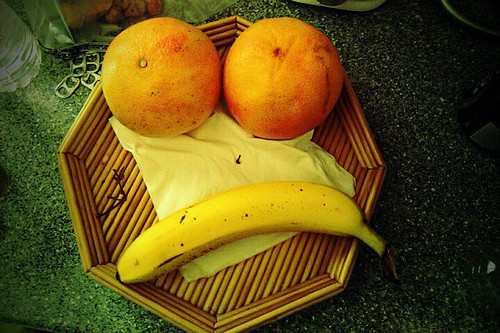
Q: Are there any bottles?
A: Yes, there is a bottle.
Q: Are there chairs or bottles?
A: Yes, there is a bottle.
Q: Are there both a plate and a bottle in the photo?
A: Yes, there are both a bottle and a plate.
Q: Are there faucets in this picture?
A: No, there are no faucets.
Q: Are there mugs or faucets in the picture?
A: No, there are no faucets or mugs.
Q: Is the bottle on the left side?
A: Yes, the bottle is on the left of the image.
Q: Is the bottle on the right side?
A: No, the bottle is on the left of the image.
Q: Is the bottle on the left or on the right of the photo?
A: The bottle is on the left of the image.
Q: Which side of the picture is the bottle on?
A: The bottle is on the left of the image.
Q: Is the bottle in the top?
A: Yes, the bottle is in the top of the image.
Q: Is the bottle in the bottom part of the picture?
A: No, the bottle is in the top of the image.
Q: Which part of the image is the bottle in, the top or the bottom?
A: The bottle is in the top of the image.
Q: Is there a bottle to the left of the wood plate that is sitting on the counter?
A: Yes, there is a bottle to the left of the plate.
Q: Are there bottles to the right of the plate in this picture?
A: No, the bottle is to the left of the plate.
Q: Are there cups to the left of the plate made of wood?
A: No, there is a bottle to the left of the plate.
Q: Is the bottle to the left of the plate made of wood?
A: Yes, the bottle is to the left of the plate.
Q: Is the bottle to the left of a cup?
A: No, the bottle is to the left of the plate.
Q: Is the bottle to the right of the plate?
A: No, the bottle is to the left of the plate.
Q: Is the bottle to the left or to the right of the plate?
A: The bottle is to the left of the plate.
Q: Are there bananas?
A: Yes, there is a banana.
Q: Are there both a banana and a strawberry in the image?
A: No, there is a banana but no strawberries.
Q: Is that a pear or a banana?
A: That is a banana.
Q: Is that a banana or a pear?
A: That is a banana.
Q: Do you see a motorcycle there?
A: No, there are no motorcycles.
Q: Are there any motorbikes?
A: No, there are no motorbikes.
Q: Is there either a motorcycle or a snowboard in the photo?
A: No, there are no motorcycles or snowboards.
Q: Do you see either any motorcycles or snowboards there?
A: No, there are no motorcycles or snowboards.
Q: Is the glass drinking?
A: Yes, the glass is drinking.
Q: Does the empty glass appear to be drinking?
A: Yes, the glass is drinking.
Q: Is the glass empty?
A: Yes, the glass is empty.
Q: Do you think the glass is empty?
A: Yes, the glass is empty.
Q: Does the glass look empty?
A: Yes, the glass is empty.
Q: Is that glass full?
A: No, the glass is empty.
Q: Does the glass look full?
A: No, the glass is empty.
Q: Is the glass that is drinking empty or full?
A: The glass is empty.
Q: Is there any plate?
A: Yes, there is a plate.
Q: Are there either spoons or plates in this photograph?
A: Yes, there is a plate.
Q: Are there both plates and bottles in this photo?
A: Yes, there are both a plate and a bottle.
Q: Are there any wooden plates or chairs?
A: Yes, there is a wood plate.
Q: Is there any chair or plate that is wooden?
A: Yes, the plate is wooden.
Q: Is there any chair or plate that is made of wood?
A: Yes, the plate is made of wood.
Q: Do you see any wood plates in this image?
A: Yes, there is a wood plate.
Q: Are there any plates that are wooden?
A: Yes, there is a plate that is wooden.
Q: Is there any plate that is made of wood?
A: Yes, there is a plate that is made of wood.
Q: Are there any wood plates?
A: Yes, there is a plate that is made of wood.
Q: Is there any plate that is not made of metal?
A: Yes, there is a plate that is made of wood.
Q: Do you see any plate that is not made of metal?
A: Yes, there is a plate that is made of wood.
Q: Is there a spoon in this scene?
A: No, there are no spoons.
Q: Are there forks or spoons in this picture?
A: No, there are no spoons or forks.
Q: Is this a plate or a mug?
A: This is a plate.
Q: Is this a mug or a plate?
A: This is a plate.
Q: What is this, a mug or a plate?
A: This is a plate.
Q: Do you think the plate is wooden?
A: Yes, the plate is wooden.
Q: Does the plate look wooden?
A: Yes, the plate is wooden.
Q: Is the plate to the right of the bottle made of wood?
A: Yes, the plate is made of wood.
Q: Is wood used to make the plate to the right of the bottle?
A: Yes, the plate is made of wood.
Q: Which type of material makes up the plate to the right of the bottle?
A: The plate is made of wood.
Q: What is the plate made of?
A: The plate is made of wood.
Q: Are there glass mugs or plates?
A: No, there is a plate but it is wooden.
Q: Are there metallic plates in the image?
A: No, there is a plate but it is wooden.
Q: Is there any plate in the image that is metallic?
A: No, there is a plate but it is wooden.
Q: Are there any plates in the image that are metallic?
A: No, there is a plate but it is wooden.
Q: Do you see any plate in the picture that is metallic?
A: No, there is a plate but it is wooden.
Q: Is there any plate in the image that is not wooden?
A: No, there is a plate but it is wooden.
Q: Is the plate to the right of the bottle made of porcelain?
A: No, the plate is made of wood.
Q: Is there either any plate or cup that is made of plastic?
A: No, there is a plate but it is made of wood.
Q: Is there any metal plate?
A: No, there is a plate but it is made of wood.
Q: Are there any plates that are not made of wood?
A: No, there is a plate but it is made of wood.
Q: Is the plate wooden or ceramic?
A: The plate is wooden.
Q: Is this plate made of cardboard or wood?
A: The plate is made of wood.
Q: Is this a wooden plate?
A: Yes, this is a wooden plate.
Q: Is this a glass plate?
A: No, this is a wooden plate.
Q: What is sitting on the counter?
A: The plate is sitting on the counter.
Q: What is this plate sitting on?
A: The plate is sitting on the counter.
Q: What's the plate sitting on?
A: The plate is sitting on the counter.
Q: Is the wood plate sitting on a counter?
A: Yes, the plate is sitting on a counter.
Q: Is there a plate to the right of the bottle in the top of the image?
A: Yes, there is a plate to the right of the bottle.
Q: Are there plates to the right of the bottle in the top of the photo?
A: Yes, there is a plate to the right of the bottle.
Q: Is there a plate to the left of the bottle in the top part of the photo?
A: No, the plate is to the right of the bottle.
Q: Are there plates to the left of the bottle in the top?
A: No, the plate is to the right of the bottle.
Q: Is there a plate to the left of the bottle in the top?
A: No, the plate is to the right of the bottle.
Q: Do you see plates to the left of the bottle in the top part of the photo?
A: No, the plate is to the right of the bottle.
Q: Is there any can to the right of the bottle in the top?
A: No, there is a plate to the right of the bottle.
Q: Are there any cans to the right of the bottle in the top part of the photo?
A: No, there is a plate to the right of the bottle.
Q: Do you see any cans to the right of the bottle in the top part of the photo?
A: No, there is a plate to the right of the bottle.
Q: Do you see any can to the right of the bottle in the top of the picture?
A: No, there is a plate to the right of the bottle.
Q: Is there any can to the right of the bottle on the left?
A: No, there is a plate to the right of the bottle.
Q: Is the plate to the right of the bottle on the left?
A: Yes, the plate is to the right of the bottle.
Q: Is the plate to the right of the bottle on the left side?
A: Yes, the plate is to the right of the bottle.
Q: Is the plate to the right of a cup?
A: No, the plate is to the right of the bottle.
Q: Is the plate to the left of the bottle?
A: No, the plate is to the right of the bottle.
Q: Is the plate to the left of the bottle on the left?
A: No, the plate is to the right of the bottle.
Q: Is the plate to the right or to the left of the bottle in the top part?
A: The plate is to the right of the bottle.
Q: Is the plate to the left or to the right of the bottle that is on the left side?
A: The plate is to the right of the bottle.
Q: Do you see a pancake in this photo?
A: No, there are no pancakes.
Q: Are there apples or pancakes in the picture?
A: No, there are no pancakes or apples.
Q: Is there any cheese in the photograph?
A: No, there is no cheese.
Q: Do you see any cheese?
A: No, there is no cheese.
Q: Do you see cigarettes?
A: No, there are no cigarettes.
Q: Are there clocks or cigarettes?
A: No, there are no cigarettes or clocks.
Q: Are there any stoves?
A: No, there are no stoves.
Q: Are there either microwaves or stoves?
A: No, there are no stoves or microwaves.